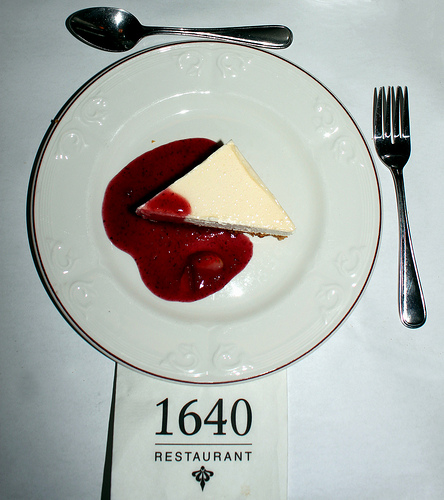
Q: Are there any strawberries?
A: Yes, there is a strawberry.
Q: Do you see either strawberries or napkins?
A: Yes, there is a strawberry.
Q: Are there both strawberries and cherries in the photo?
A: No, there is a strawberry but no cherries.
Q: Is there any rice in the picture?
A: No, there is no rice.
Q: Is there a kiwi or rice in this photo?
A: No, there are no rice or kiwis.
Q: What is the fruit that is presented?
A: The fruit is a strawberry.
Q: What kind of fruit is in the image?
A: The fruit is a strawberry.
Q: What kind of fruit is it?
A: The fruit is a strawberry.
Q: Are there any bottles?
A: No, there are no bottles.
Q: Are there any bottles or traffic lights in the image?
A: No, there are no bottles or traffic lights.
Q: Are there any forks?
A: Yes, there is a fork.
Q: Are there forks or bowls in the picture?
A: Yes, there is a fork.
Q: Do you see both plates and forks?
A: Yes, there are both a fork and a plate.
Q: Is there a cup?
A: No, there are no cups.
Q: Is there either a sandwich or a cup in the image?
A: No, there are no cups or sandwiches.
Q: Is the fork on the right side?
A: Yes, the fork is on the right of the image.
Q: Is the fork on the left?
A: No, the fork is on the right of the image.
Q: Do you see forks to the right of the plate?
A: Yes, there is a fork to the right of the plate.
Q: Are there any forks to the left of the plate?
A: No, the fork is to the right of the plate.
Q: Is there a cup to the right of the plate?
A: No, there is a fork to the right of the plate.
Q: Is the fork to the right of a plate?
A: Yes, the fork is to the right of a plate.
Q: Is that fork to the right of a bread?
A: No, the fork is to the right of a plate.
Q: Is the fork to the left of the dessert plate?
A: No, the fork is to the right of the plate.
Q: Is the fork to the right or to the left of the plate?
A: The fork is to the right of the plate.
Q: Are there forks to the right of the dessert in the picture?
A: Yes, there is a fork to the right of the dessert.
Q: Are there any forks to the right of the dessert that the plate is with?
A: Yes, there is a fork to the right of the dessert.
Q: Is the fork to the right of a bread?
A: No, the fork is to the right of the dessert.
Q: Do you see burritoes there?
A: No, there are no burritoes.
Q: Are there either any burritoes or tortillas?
A: No, there are no burritoes or tortillas.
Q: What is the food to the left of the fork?
A: The food is a dessert.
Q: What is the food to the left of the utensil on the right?
A: The food is a dessert.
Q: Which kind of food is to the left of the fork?
A: The food is a dessert.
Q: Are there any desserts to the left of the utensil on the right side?
A: Yes, there is a dessert to the left of the fork.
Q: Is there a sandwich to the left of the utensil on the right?
A: No, there is a dessert to the left of the fork.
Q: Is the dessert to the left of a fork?
A: Yes, the dessert is to the left of a fork.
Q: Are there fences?
A: No, there are no fences.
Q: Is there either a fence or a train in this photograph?
A: No, there are no fences or trains.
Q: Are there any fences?
A: No, there are no fences.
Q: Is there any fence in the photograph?
A: No, there are no fences.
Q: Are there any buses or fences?
A: No, there are no fences or buses.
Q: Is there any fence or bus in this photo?
A: No, there are no fences or buses.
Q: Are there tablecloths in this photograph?
A: Yes, there is a tablecloth.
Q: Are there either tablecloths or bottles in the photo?
A: Yes, there is a tablecloth.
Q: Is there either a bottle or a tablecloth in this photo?
A: Yes, there is a tablecloth.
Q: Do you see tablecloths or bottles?
A: Yes, there is a tablecloth.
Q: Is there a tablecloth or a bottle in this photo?
A: Yes, there is a tablecloth.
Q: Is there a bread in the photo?
A: No, there is no breads.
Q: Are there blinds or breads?
A: No, there are no breads or blinds.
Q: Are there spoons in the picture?
A: Yes, there is a spoon.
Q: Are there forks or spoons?
A: Yes, there is a spoon.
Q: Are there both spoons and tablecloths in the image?
A: Yes, there are both a spoon and a tablecloth.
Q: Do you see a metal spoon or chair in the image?
A: Yes, there is a metal spoon.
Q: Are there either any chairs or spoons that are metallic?
A: Yes, the spoon is metallic.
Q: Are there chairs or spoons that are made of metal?
A: Yes, the spoon is made of metal.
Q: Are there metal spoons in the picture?
A: Yes, there is a metal spoon.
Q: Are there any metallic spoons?
A: Yes, there is a metal spoon.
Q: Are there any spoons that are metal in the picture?
A: Yes, there is a metal spoon.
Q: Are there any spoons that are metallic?
A: Yes, there is a spoon that is metallic.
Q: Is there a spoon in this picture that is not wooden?
A: Yes, there is a metallic spoon.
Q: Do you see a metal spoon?
A: Yes, there is a spoon that is made of metal.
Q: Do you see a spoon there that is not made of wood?
A: Yes, there is a spoon that is made of metal.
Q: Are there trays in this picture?
A: No, there are no trays.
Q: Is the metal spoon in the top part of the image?
A: Yes, the spoon is in the top of the image.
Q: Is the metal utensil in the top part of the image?
A: Yes, the spoon is in the top of the image.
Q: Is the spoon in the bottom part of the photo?
A: No, the spoon is in the top of the image.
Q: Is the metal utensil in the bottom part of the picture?
A: No, the spoon is in the top of the image.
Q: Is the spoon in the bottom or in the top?
A: The spoon is in the top of the image.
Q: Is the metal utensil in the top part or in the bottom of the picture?
A: The spoon is in the top of the image.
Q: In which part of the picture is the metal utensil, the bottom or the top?
A: The spoon is in the top of the image.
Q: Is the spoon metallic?
A: Yes, the spoon is metallic.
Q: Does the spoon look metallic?
A: Yes, the spoon is metallic.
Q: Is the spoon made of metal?
A: Yes, the spoon is made of metal.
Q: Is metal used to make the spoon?
A: Yes, the spoon is made of metal.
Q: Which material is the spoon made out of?
A: The spoon is made of metal.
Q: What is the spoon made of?
A: The spoon is made of metal.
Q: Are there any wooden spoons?
A: No, there is a spoon but it is metallic.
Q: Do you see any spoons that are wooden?
A: No, there is a spoon but it is metallic.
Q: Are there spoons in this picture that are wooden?
A: No, there is a spoon but it is metallic.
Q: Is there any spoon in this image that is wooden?
A: No, there is a spoon but it is metallic.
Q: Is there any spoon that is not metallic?
A: No, there is a spoon but it is metallic.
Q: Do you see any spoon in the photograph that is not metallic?
A: No, there is a spoon but it is metallic.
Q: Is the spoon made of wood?
A: No, the spoon is made of metal.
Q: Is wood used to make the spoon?
A: No, the spoon is made of metal.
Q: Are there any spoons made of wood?
A: No, there is a spoon but it is made of metal.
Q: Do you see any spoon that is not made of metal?
A: No, there is a spoon but it is made of metal.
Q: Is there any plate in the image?
A: Yes, there is a plate.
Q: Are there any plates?
A: Yes, there is a plate.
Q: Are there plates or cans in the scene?
A: Yes, there is a plate.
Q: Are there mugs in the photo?
A: No, there are no mugs.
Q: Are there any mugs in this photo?
A: No, there are no mugs.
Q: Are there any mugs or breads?
A: No, there are no mugs or breads.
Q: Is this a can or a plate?
A: This is a plate.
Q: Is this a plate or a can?
A: This is a plate.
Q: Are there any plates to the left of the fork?
A: Yes, there is a plate to the left of the fork.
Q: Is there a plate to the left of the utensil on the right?
A: Yes, there is a plate to the left of the fork.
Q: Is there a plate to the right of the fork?
A: No, the plate is to the left of the fork.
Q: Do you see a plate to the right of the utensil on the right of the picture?
A: No, the plate is to the left of the fork.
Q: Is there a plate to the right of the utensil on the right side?
A: No, the plate is to the left of the fork.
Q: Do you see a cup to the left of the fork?
A: No, there is a plate to the left of the fork.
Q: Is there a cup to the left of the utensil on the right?
A: No, there is a plate to the left of the fork.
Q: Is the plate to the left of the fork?
A: Yes, the plate is to the left of the fork.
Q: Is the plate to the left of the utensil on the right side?
A: Yes, the plate is to the left of the fork.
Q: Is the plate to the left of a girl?
A: No, the plate is to the left of the fork.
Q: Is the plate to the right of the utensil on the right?
A: No, the plate is to the left of the fork.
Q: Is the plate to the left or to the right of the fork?
A: The plate is to the left of the fork.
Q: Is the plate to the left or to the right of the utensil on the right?
A: The plate is to the left of the fork.